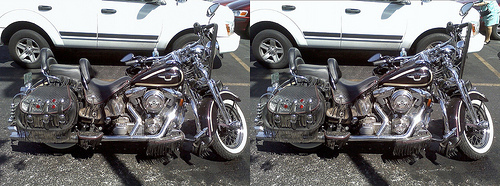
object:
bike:
[8, 1, 248, 161]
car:
[0, 0, 239, 69]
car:
[227, 1, 252, 37]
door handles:
[99, 8, 118, 14]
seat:
[41, 46, 131, 102]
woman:
[474, 0, 500, 44]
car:
[250, 0, 487, 69]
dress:
[478, 1, 500, 27]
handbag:
[476, 3, 490, 16]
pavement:
[0, 47, 249, 184]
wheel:
[210, 98, 249, 159]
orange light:
[225, 23, 232, 36]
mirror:
[207, 4, 221, 16]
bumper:
[216, 33, 242, 54]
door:
[98, 0, 162, 53]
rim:
[17, 37, 41, 62]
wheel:
[7, 28, 50, 69]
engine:
[79, 86, 186, 136]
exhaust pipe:
[9, 106, 178, 143]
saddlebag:
[14, 85, 77, 143]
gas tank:
[131, 60, 186, 88]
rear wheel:
[35, 138, 80, 152]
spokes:
[218, 104, 243, 145]